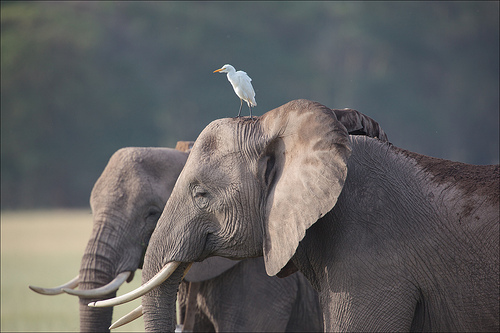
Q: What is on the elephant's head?
A: A bird.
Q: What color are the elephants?
A: Grey.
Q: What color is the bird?
A: White.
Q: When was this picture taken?
A: Daytime.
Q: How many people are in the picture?
A: 0.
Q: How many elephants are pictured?
A: 2.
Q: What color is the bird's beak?
A: Orange.